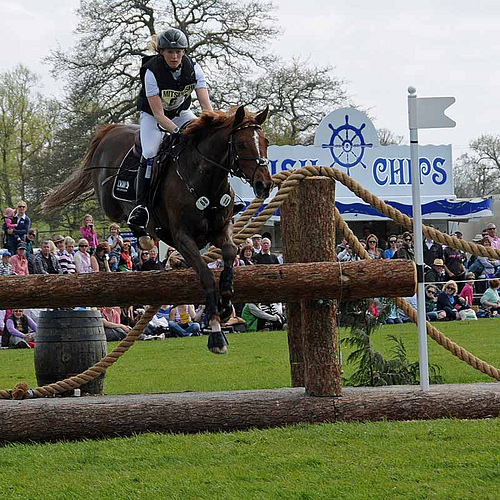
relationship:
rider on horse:
[125, 24, 219, 242] [33, 100, 273, 355]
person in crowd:
[1, 199, 31, 252] [0, 198, 500, 349]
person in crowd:
[79, 212, 100, 250] [0, 198, 500, 349]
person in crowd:
[105, 224, 125, 252] [0, 198, 500, 349]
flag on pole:
[405, 94, 460, 131] [403, 83, 472, 394]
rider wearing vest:
[125, 24, 219, 242] [134, 48, 202, 123]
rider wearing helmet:
[125, 24, 219, 242] [153, 27, 190, 74]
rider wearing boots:
[125, 24, 219, 242] [122, 201, 153, 239]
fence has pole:
[1, 167, 496, 441] [291, 169, 348, 400]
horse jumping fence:
[33, 100, 273, 355] [1, 167, 496, 441]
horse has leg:
[33, 100, 273, 355] [168, 228, 232, 360]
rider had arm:
[125, 24, 219, 242] [188, 59, 222, 121]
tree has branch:
[19, 0, 273, 235] [177, 7, 278, 72]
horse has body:
[33, 100, 273, 355] [85, 120, 215, 254]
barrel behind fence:
[27, 298, 130, 402] [1, 167, 496, 441]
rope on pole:
[0, 159, 499, 403] [291, 169, 348, 400]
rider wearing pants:
[125, 24, 219, 242] [135, 107, 210, 167]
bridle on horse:
[223, 123, 274, 198] [33, 100, 273, 355]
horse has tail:
[33, 100, 273, 355] [24, 115, 122, 229]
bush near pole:
[339, 242, 449, 393] [403, 83, 472, 394]